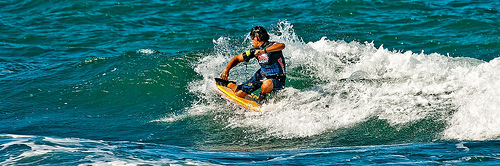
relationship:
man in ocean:
[245, 23, 284, 85] [9, 8, 490, 165]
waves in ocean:
[29, 52, 162, 122] [9, 8, 490, 165]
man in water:
[245, 23, 284, 85] [316, 27, 499, 139]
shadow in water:
[200, 121, 291, 158] [316, 27, 499, 139]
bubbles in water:
[219, 117, 264, 157] [316, 27, 499, 139]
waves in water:
[29, 52, 162, 122] [316, 27, 499, 139]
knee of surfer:
[260, 85, 268, 91] [237, 11, 292, 103]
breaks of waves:
[335, 35, 364, 50] [29, 52, 162, 122]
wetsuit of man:
[251, 46, 282, 84] [245, 23, 284, 85]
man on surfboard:
[245, 23, 284, 85] [209, 71, 255, 123]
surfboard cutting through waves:
[209, 71, 255, 123] [29, 52, 162, 122]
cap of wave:
[371, 46, 400, 67] [296, 22, 473, 111]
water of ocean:
[316, 27, 499, 139] [9, 8, 490, 165]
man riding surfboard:
[245, 23, 284, 85] [209, 71, 255, 123]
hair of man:
[243, 22, 272, 39] [245, 23, 284, 85]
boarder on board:
[240, 20, 285, 84] [213, 80, 257, 119]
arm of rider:
[254, 39, 302, 72] [237, 15, 279, 91]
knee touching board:
[242, 74, 249, 103] [213, 80, 257, 119]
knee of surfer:
[242, 74, 249, 103] [237, 11, 292, 103]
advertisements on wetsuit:
[255, 53, 272, 72] [251, 46, 282, 84]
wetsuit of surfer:
[251, 46, 282, 84] [237, 11, 292, 103]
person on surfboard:
[247, 21, 298, 92] [209, 71, 255, 123]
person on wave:
[247, 21, 298, 92] [296, 22, 473, 111]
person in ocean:
[247, 21, 298, 92] [9, 8, 490, 165]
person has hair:
[247, 21, 298, 92] [243, 22, 272, 39]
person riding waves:
[247, 21, 298, 92] [29, 52, 162, 122]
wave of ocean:
[296, 22, 473, 111] [9, 8, 490, 165]